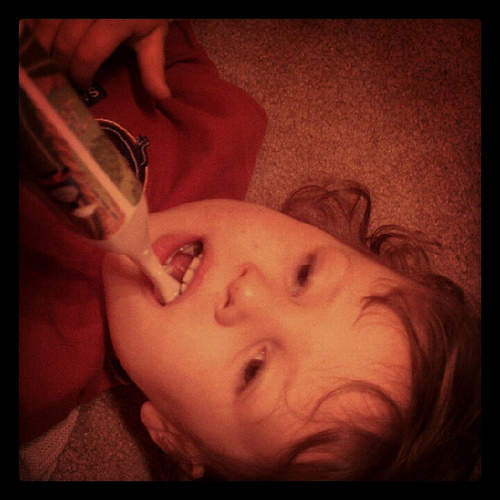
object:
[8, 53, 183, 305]
toothbrush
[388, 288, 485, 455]
hair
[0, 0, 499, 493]
boy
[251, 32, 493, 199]
carpet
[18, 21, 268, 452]
shirt